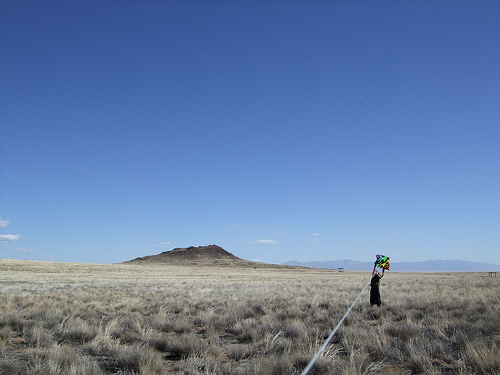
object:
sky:
[12, 11, 485, 137]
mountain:
[124, 240, 293, 265]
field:
[50, 278, 264, 373]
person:
[368, 252, 391, 305]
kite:
[374, 253, 391, 270]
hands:
[374, 263, 377, 266]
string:
[299, 290, 360, 366]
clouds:
[0, 231, 29, 245]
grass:
[455, 315, 484, 342]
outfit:
[368, 273, 384, 304]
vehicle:
[337, 266, 346, 272]